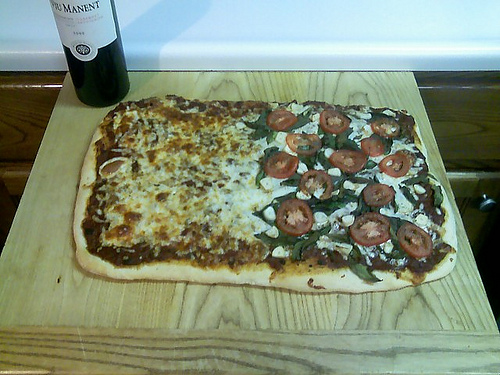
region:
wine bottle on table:
[66, 4, 141, 116]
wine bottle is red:
[69, 3, 139, 111]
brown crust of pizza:
[63, 121, 484, 301]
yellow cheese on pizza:
[118, 109, 273, 284]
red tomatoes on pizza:
[281, 103, 423, 288]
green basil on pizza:
[249, 96, 415, 281]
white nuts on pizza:
[268, 106, 443, 291]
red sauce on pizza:
[79, 151, 195, 270]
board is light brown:
[86, 86, 486, 356]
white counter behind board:
[126, 1, 447, 70]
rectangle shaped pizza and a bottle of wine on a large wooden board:
[4, 3, 492, 371]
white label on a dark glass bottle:
[41, 0, 119, 62]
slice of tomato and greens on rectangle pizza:
[391, 217, 436, 264]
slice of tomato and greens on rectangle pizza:
[274, 196, 319, 248]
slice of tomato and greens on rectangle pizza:
[293, 168, 351, 210]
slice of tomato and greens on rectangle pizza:
[319, 108, 355, 149]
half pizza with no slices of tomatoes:
[72, 93, 262, 282]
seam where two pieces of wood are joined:
[3, 327, 498, 338]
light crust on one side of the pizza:
[76, 264, 450, 294]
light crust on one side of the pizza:
[69, 128, 96, 268]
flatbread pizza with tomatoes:
[74, 97, 456, 292]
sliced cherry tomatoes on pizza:
[268, 106, 435, 258]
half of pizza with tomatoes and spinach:
[249, 105, 445, 280]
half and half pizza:
[71, 96, 462, 292]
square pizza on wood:
[73, 96, 460, 301]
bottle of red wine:
[49, 0, 133, 107]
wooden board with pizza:
[3, 72, 497, 372]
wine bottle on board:
[48, 2, 134, 110]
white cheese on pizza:
[263, 104, 434, 268]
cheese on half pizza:
[110, 105, 255, 254]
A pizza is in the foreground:
[52, 93, 462, 308]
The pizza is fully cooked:
[60, 92, 460, 317]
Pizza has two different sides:
[57, 86, 463, 309]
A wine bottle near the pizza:
[37, 0, 468, 300]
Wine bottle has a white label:
[45, 0, 130, 67]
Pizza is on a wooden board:
[0, 65, 495, 371]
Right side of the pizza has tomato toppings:
[263, 90, 438, 280]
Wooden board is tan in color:
[0, 68, 495, 368]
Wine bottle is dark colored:
[41, 0, 152, 111]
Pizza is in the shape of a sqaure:
[69, 82, 461, 311]